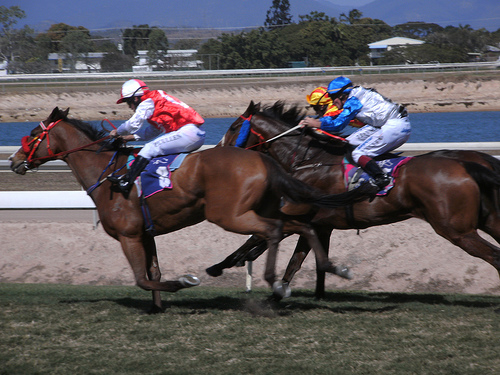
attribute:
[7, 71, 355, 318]
man — racing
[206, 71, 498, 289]
man — racing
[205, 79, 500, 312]
man — racing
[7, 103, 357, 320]
horse — brown, racing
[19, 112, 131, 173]
briddles — red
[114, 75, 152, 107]
helmet — red, white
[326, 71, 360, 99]
helmet — blue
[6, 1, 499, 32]
sky — blue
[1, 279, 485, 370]
grass — green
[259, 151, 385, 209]
tail — black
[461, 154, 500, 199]
tail — black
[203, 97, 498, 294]
horse — black, racing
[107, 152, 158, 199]
boots — black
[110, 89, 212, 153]
shirt — red, white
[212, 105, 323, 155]
briddles — white, blue, red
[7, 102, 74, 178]
head — brown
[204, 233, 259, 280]
leg — black